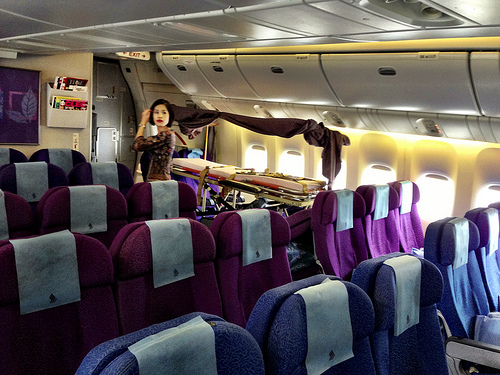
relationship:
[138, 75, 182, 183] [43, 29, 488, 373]
woman on plane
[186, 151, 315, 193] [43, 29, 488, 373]
stretcher on plane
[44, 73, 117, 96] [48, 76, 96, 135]
magazines in rack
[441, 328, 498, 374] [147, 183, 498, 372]
armrest on seats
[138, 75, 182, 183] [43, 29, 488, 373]
woman inside plane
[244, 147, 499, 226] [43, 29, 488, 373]
windows on plane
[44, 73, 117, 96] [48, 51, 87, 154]
magazines on wall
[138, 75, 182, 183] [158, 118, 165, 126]
woman has lipstick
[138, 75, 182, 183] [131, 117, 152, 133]
woman has watch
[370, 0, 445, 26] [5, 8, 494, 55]
light on ceiling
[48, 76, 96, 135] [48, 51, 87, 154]
rack on wall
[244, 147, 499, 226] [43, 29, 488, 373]
windows inside plane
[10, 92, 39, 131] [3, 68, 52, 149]
leaves on painting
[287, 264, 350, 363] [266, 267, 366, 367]
cover on headrest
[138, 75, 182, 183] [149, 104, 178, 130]
woman strokes hair